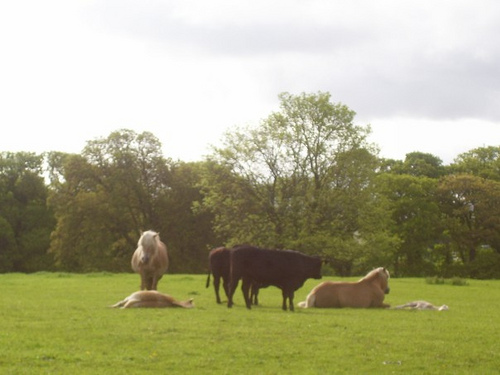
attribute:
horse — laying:
[121, 287, 194, 309]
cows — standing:
[205, 241, 327, 311]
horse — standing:
[127, 228, 169, 288]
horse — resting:
[296, 264, 393, 309]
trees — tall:
[215, 79, 378, 235]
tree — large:
[191, 92, 369, 279]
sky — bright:
[3, 26, 498, 175]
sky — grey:
[0, 0, 499, 203]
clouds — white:
[0, 1, 498, 201]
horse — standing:
[131, 231, 168, 291]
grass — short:
[75, 193, 490, 360]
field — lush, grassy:
[0, 276, 498, 373]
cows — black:
[203, 230, 330, 319]